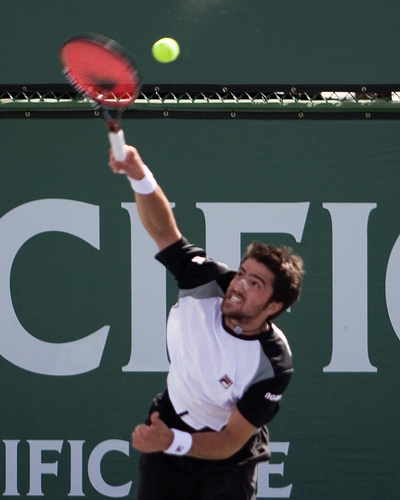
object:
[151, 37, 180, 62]
tennis ball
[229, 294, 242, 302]
teeth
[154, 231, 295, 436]
tee shirt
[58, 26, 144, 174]
tennis racket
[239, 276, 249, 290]
breathing strip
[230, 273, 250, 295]
nose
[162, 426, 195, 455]
wrist band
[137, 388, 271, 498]
shorts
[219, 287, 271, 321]
stubble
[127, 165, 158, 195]
wristband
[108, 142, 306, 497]
man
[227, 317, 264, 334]
necklace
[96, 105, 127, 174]
handle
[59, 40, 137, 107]
strings